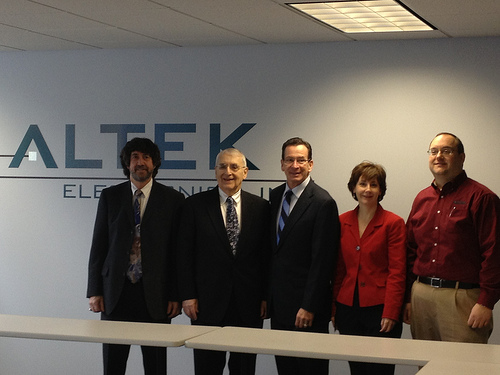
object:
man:
[179, 146, 270, 375]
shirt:
[276, 174, 311, 244]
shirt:
[219, 188, 242, 233]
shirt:
[131, 177, 153, 222]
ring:
[304, 321, 308, 323]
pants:
[337, 305, 402, 375]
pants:
[101, 277, 167, 375]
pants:
[189, 293, 261, 375]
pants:
[269, 304, 330, 375]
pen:
[449, 207, 456, 217]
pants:
[410, 281, 493, 344]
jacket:
[330, 203, 406, 322]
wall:
[0, 36, 500, 374]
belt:
[412, 274, 479, 289]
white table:
[0, 314, 500, 375]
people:
[87, 132, 500, 375]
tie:
[277, 190, 292, 244]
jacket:
[86, 178, 185, 318]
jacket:
[175, 184, 270, 323]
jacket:
[267, 177, 340, 326]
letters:
[8, 123, 261, 171]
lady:
[332, 161, 407, 375]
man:
[266, 136, 342, 375]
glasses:
[284, 157, 311, 163]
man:
[88, 137, 188, 375]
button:
[437, 210, 440, 213]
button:
[434, 227, 438, 230]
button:
[434, 243, 438, 246]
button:
[432, 259, 435, 262]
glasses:
[427, 149, 461, 155]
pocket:
[445, 209, 468, 233]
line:
[0, 175, 288, 182]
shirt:
[406, 169, 500, 310]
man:
[403, 132, 500, 371]